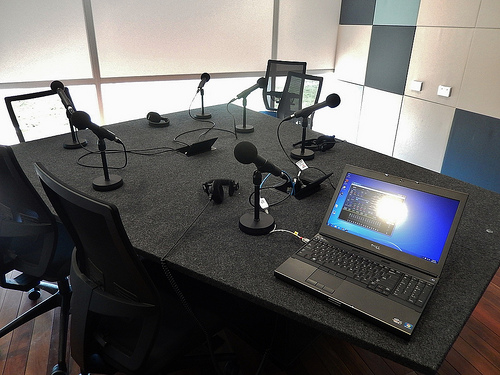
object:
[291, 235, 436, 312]
keyboard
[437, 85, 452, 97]
switch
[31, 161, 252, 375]
chair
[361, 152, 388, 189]
ground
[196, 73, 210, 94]
microphone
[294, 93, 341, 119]
microphone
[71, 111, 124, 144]
microphone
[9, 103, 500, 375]
desk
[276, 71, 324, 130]
chair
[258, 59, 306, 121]
chair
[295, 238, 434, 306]
laptop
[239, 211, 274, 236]
black wheels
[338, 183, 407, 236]
document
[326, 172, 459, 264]
screen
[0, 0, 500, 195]
wall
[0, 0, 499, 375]
office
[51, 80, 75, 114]
microphone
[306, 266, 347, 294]
pad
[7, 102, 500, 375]
bad square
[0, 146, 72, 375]
chair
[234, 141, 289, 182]
microphone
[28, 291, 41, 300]
wheel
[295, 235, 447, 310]
lap top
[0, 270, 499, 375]
floor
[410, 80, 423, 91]
thermostat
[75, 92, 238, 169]
cords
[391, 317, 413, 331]
logo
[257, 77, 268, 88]
microphone